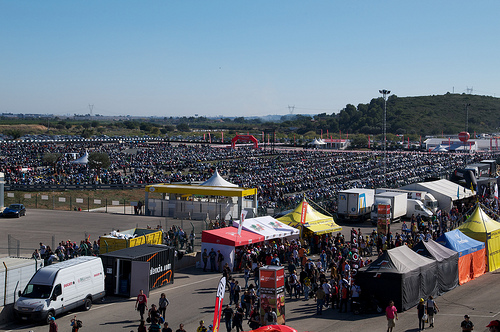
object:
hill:
[273, 93, 500, 133]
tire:
[82, 299, 92, 311]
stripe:
[147, 253, 158, 262]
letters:
[160, 266, 162, 272]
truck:
[336, 188, 376, 221]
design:
[357, 193, 366, 215]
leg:
[316, 302, 320, 316]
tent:
[395, 178, 475, 220]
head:
[388, 300, 394, 306]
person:
[385, 300, 398, 332]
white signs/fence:
[2, 189, 147, 216]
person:
[416, 298, 425, 332]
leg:
[141, 307, 145, 320]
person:
[135, 289, 149, 321]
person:
[289, 268, 302, 300]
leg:
[289, 286, 293, 300]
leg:
[294, 287, 298, 301]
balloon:
[458, 132, 470, 142]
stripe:
[458, 135, 468, 137]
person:
[314, 286, 327, 316]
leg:
[319, 303, 323, 316]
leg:
[331, 297, 335, 312]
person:
[331, 281, 340, 311]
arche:
[231, 135, 258, 149]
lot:
[2, 139, 499, 224]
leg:
[234, 295, 240, 309]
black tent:
[411, 238, 459, 295]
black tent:
[357, 245, 436, 313]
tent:
[229, 215, 304, 267]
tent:
[357, 245, 437, 312]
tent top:
[276, 193, 342, 235]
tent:
[433, 228, 485, 285]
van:
[11, 255, 105, 324]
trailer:
[98, 243, 175, 298]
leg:
[390, 320, 396, 330]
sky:
[0, 0, 497, 116]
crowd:
[281, 227, 368, 316]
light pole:
[383, 93, 387, 189]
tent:
[457, 202, 500, 272]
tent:
[276, 193, 342, 255]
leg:
[301, 284, 310, 302]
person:
[303, 274, 313, 301]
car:
[2, 203, 26, 218]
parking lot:
[1, 203, 209, 281]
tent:
[198, 166, 240, 187]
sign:
[75, 198, 83, 203]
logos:
[250, 223, 265, 232]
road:
[15, 199, 494, 329]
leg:
[387, 321, 391, 331]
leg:
[429, 313, 432, 328]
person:
[247, 307, 262, 332]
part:
[176, 271, 206, 284]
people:
[425, 295, 439, 328]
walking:
[383, 295, 440, 332]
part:
[213, 228, 229, 233]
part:
[384, 175, 386, 181]